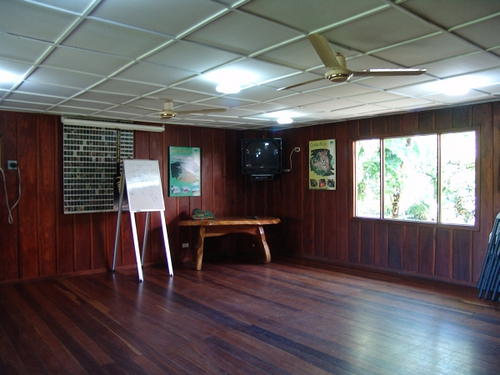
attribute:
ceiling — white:
[1, 2, 497, 127]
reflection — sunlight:
[345, 309, 475, 374]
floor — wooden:
[5, 243, 498, 373]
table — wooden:
[179, 213, 277, 273]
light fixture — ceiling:
[213, 80, 241, 98]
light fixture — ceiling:
[275, 115, 293, 127]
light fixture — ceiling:
[441, 85, 471, 100]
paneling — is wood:
[1, 106, 499, 282]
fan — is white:
[266, 26, 443, 109]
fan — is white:
[108, 80, 244, 124]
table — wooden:
[169, 179, 299, 274]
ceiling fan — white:
[274, 34, 429, 98]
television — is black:
[238, 135, 288, 180]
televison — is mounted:
[219, 120, 320, 190]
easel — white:
[89, 142, 196, 297]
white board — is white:
[106, 153, 175, 283]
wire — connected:
[0, 155, 34, 225]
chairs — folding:
[478, 209, 498, 301]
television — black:
[236, 132, 286, 182]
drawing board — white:
[109, 156, 179, 288]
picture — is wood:
[293, 122, 356, 225]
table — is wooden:
[178, 216, 282, 267]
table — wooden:
[173, 212, 283, 272]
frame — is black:
[166, 144, 202, 198]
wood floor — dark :
[5, 251, 497, 371]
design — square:
[108, 20, 367, 120]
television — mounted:
[215, 119, 322, 206]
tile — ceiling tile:
[89, 70, 165, 99]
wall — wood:
[1, 123, 340, 275]